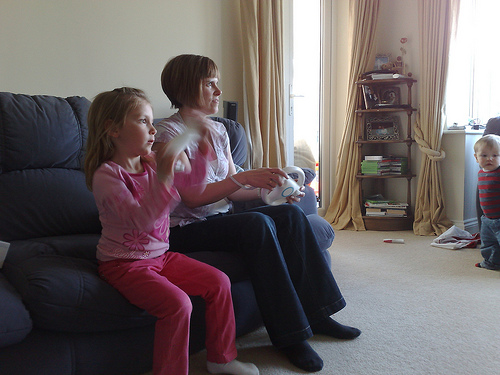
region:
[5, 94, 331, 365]
a dark blue couch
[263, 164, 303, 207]
a Wii video game controller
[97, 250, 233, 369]
a pair of pink child's pants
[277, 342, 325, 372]
a woman's black sock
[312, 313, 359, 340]
a woman's black sock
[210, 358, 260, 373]
a girl's white sock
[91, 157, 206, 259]
a girl's pink top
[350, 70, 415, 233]
a wooden shelf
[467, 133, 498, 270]
small young boy stadnding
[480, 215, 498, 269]
pair of baby boy's jeans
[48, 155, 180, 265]
girl's shirt is pink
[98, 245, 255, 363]
girl's pants are pink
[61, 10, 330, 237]
girl and woman holding controllers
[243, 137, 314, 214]
controller is a steering wheel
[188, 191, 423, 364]
woman is wearing blue jeans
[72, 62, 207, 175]
girl is moving controller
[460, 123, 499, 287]
little boy is standing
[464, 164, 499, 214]
boy's shirt is striped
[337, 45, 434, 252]
bookshelf next to window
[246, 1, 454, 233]
the curtains are yellow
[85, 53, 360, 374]
a woman and a girl sitting on a couch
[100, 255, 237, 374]
a girl wearing pink pants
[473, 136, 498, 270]
a blond boy standing in a living room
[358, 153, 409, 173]
a stak of books on a shelf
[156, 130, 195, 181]
girl holding a gaming controller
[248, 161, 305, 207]
woman holding a plastic white wheel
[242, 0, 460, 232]
beige drapes on the window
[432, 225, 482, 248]
a white and red plastic bag on the carpet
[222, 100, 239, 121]
a black and gray speaker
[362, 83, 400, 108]
framed pictures on a shelf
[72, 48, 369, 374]
two people playing video games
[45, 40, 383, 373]
two people playing wii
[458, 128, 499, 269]
the boy on the carpet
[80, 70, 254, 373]
the girl sitting down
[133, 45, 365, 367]
the woman sitting down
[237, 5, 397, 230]
the curtains are open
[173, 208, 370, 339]
the woman wearing blue jeans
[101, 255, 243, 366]
the girl wearing pink pants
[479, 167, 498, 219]
the boy wearing a striped shirt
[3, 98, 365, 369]
the sofa is blue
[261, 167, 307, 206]
Steering wheel video game control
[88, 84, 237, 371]
Young girl wearing dark pink pants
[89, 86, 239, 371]
Young girl wearing light floral print shirt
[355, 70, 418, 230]
Five shelf book stand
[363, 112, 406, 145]
Stereo sitting on shelf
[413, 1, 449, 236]
Rope tied curtain panel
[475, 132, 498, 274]
Toddler wearing gray and red shirt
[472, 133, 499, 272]
Toddler wearing baggy blue pants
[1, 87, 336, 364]
Overstuffed style blue couch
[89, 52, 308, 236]
Adult and child playing video game